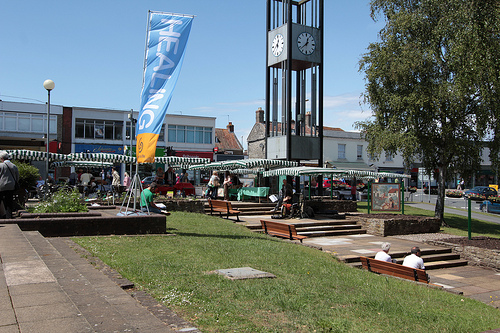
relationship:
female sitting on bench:
[374, 242, 395, 263] [358, 259, 445, 289]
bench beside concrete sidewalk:
[206, 197, 244, 222] [336, 234, 406, 253]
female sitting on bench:
[374, 242, 395, 263] [350, 254, 430, 288]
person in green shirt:
[139, 185, 171, 217] [142, 187, 156, 210]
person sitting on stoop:
[139, 185, 171, 217] [16, 205, 166, 236]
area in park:
[79, 210, 499, 331] [6, 182, 499, 332]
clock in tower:
[295, 27, 319, 65] [258, 12, 338, 182]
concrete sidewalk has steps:
[336, 234, 406, 253] [208, 195, 469, 273]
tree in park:
[370, 6, 492, 222] [1, 99, 499, 331]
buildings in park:
[7, 97, 499, 196] [2, 94, 498, 208]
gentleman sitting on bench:
[403, 235, 423, 275] [361, 254, 441, 280]